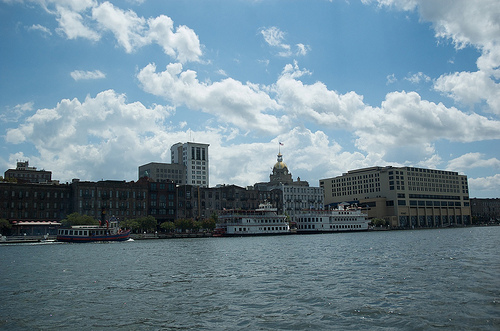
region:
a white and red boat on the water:
[55, 218, 132, 243]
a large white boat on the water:
[209, 202, 294, 237]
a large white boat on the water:
[293, 201, 371, 233]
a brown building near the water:
[1, 180, 73, 232]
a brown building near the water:
[70, 179, 149, 226]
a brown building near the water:
[146, 178, 176, 227]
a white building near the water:
[168, 138, 208, 218]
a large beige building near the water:
[318, 165, 475, 227]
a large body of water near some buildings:
[0, 223, 499, 328]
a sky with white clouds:
[0, 2, 498, 187]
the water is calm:
[64, 261, 139, 305]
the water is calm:
[256, 250, 329, 287]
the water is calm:
[383, 268, 460, 320]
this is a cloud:
[141, 10, 210, 77]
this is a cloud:
[199, 73, 274, 132]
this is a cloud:
[81, 90, 130, 144]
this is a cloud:
[380, 81, 457, 150]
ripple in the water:
[224, 296, 258, 310]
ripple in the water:
[317, 295, 346, 317]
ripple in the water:
[152, 285, 175, 305]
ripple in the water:
[139, 287, 161, 299]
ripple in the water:
[383, 277, 416, 302]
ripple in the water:
[277, 297, 301, 318]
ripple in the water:
[378, 271, 405, 287]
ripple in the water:
[297, 287, 312, 294]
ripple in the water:
[237, 264, 260, 283]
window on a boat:
[59, 228, 66, 235]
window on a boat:
[64, 228, 69, 235]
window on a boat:
[67, 228, 74, 237]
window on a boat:
[72, 228, 79, 235]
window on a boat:
[77, 228, 84, 237]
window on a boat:
[82, 229, 87, 237]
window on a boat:
[93, 228, 99, 235]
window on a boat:
[99, 228, 104, 235]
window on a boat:
[108, 221, 113, 228]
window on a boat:
[113, 221, 118, 228]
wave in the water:
[342, 302, 367, 314]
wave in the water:
[260, 278, 280, 296]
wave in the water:
[388, 282, 420, 312]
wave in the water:
[270, 283, 289, 302]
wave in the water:
[307, 280, 327, 299]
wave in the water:
[333, 267, 366, 284]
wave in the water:
[416, 272, 441, 294]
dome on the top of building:
[270, 157, 286, 173]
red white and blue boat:
[55, 223, 124, 245]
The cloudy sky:
[1, 12, 492, 194]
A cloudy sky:
[0, 14, 490, 204]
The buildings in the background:
[13, 135, 477, 260]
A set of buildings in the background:
[4, 132, 480, 257]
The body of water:
[14, 223, 494, 329]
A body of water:
[8, 220, 493, 328]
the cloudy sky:
[2, 14, 497, 198]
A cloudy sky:
[2, 20, 492, 182]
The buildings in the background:
[9, 137, 486, 242]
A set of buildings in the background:
[15, 135, 490, 250]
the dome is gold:
[272, 157, 286, 170]